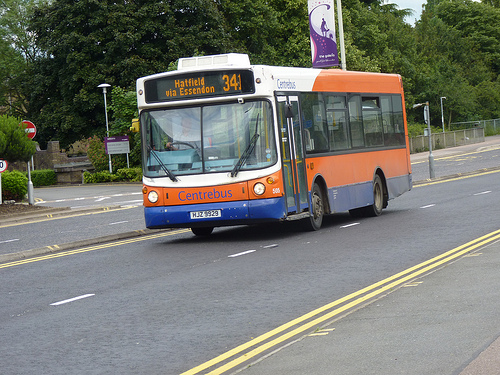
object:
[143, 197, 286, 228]
bottom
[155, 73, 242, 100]
marquee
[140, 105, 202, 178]
front window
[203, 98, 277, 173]
front window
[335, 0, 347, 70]
pole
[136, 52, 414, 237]
bus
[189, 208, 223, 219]
license plate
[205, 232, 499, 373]
curb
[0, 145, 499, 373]
driveway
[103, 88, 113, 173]
pole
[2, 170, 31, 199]
bush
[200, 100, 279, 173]
windshield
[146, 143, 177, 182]
wiper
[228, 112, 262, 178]
wiper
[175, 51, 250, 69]
air conditioner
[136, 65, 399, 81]
roof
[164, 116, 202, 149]
driver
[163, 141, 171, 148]
hand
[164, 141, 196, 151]
wheel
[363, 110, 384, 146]
window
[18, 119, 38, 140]
sign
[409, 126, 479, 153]
fence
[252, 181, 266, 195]
headlight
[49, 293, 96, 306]
median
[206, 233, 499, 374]
lines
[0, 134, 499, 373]
road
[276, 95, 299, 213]
doors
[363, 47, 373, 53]
leaves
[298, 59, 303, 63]
leaves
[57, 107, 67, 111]
leaves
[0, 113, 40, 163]
tree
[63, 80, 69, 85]
leaves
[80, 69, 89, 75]
leaves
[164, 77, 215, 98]
destination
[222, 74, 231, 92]
number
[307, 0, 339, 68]
banner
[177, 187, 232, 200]
name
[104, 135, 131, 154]
sign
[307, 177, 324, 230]
front tire